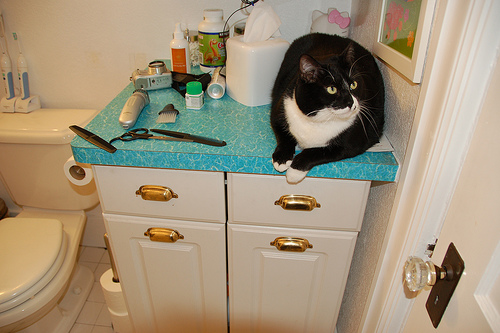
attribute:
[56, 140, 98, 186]
toilet paper — roll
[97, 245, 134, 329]
paper — toilet paper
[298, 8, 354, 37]
kitty — hello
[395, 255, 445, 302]
door knob — crystal 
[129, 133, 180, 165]
countertop — turquoise, laminated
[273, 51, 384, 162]
cat — black , white 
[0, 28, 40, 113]
electric toothbrushes — blue , white , electric 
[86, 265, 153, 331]
toilet paper — roll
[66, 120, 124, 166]
hair comb — black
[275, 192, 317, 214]
golden handle — golden 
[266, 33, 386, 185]
cat — black, white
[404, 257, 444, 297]
door knob — bathroom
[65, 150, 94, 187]
toilet paper — white, roll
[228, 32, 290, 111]
tissue dispenser — white, facial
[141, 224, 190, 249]
golden handle — golden 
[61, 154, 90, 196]
toilet paper — roll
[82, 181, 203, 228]
handles — gold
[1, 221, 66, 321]
bowl — white 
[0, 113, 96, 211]
tank — white 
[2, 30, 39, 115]
toothbrush — white, electric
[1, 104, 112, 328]
toilet — off-white, ceramic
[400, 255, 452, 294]
knob — clear, door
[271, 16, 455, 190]
cat — black, white, laying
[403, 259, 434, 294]
knob — faux crystal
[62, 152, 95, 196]
toilet paper — roll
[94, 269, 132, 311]
toilet paper — roll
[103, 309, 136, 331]
toilet paper — roll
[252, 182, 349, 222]
drawer pulls — gold 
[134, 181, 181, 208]
handle — golden 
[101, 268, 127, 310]
toilet paper — rolls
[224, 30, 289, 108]
box — white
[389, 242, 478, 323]
door handle — metal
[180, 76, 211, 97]
lid — green 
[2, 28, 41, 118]
toothbrushes — electric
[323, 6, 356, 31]
bow — pink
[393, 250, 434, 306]
knob — crystal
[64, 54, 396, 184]
countertop — blue 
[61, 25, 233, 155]
items — many